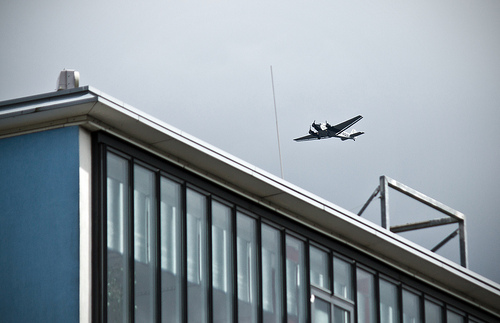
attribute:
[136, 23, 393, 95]
clouds — white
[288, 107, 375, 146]
plane — flying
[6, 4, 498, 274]
cloud — white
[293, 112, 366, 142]
plane — flying, white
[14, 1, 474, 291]
sky — blue, dark, grey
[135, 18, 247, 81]
clouds — white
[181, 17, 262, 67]
clouds — white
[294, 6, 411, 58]
sky — blue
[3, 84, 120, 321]
wall — blue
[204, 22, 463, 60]
sky — clear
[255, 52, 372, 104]
clouds — white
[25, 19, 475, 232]
sky — blue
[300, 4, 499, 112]
clouds — white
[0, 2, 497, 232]
sky — blue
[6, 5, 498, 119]
sky — blue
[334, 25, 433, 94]
clouds — white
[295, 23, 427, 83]
clouds — white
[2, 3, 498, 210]
sky — blue